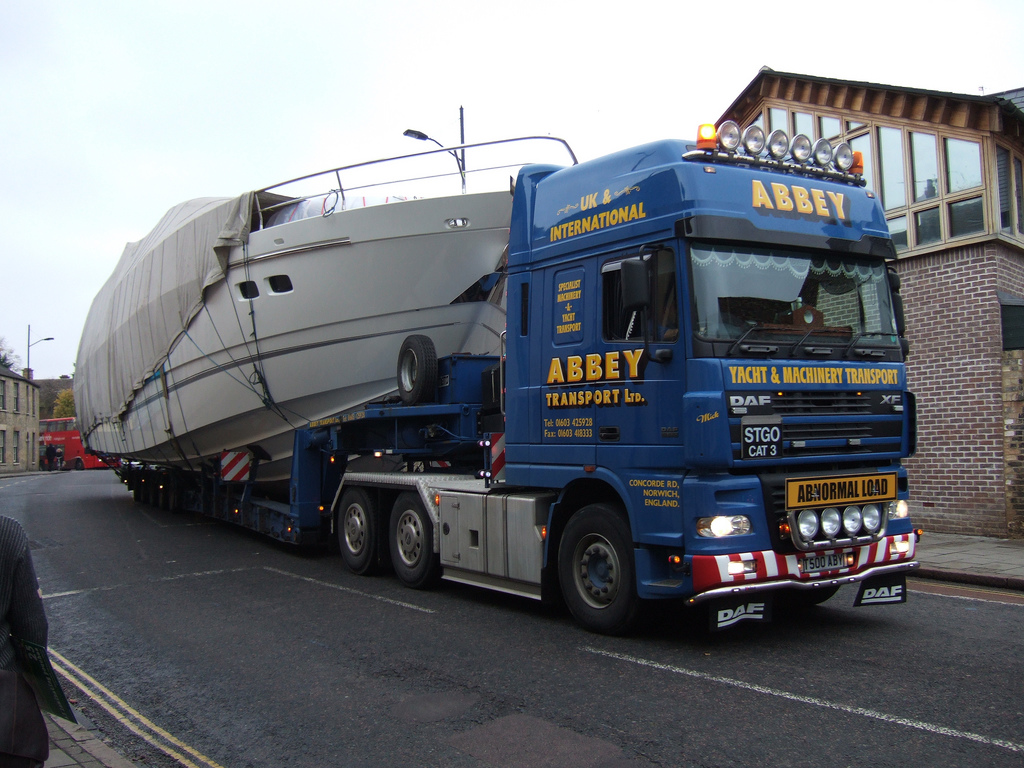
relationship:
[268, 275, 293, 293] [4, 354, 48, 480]
window on a building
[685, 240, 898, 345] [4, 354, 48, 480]
window on a building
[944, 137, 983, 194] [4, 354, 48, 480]
window on a building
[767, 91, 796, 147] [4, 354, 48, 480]
window on a building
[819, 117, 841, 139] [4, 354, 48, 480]
window on a building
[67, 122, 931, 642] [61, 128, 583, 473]
truck for moving wide loads and heavy equipment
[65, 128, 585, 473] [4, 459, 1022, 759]
boat transported road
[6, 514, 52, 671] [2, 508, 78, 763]
arm of person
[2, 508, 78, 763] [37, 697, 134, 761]
person watching from sidewalk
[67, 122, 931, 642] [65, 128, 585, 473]
truck carrying boat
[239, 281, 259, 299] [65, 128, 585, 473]
window on boat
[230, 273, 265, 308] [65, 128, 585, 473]
window on boat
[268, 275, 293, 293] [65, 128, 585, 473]
window on boat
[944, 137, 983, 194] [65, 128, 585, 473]
window on boat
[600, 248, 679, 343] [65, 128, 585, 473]
window on boat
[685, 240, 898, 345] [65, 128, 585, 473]
window on boat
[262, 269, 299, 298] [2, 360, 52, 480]
window on building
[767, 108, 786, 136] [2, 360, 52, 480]
window on building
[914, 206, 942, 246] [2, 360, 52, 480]
window on building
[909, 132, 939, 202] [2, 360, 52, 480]
window on building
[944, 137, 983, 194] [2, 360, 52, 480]
window on building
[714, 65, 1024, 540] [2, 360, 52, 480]
brick building on building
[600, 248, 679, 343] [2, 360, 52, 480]
window on building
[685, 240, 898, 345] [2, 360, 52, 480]
window on building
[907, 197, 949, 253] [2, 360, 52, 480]
window on building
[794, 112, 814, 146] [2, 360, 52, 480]
window on building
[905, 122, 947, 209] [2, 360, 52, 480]
window on building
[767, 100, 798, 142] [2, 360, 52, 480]
window on building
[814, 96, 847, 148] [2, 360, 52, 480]
window on building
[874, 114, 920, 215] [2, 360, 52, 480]
window on building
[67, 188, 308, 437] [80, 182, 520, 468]
canvas on cabin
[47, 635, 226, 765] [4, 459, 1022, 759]
double line on road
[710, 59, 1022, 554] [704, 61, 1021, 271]
brick building has second floor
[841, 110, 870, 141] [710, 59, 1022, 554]
window has brick building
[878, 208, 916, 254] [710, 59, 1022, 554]
window has brick building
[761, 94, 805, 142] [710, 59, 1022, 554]
window has brick building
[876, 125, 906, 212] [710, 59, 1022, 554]
window has brick building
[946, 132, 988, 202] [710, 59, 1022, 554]
window has brick building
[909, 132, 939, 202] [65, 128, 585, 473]
window on boat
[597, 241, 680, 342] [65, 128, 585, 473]
window on boat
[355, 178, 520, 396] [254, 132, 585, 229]
boat's bow has railing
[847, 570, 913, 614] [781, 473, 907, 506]
sign says abnormal load